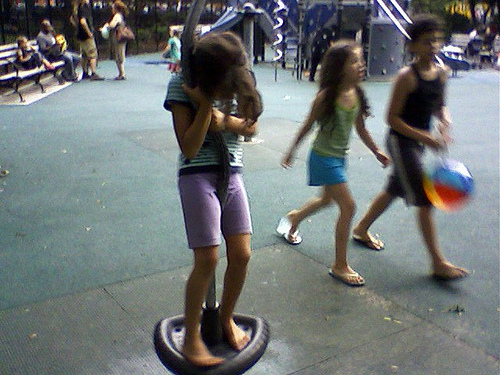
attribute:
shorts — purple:
[181, 165, 253, 242]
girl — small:
[153, 26, 282, 373]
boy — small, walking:
[392, 13, 474, 294]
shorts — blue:
[306, 142, 348, 189]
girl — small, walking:
[295, 30, 368, 265]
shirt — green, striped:
[324, 81, 360, 167]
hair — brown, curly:
[192, 35, 260, 90]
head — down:
[185, 33, 244, 97]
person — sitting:
[15, 32, 42, 70]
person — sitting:
[30, 20, 79, 71]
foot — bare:
[220, 312, 251, 351]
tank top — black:
[403, 58, 451, 143]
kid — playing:
[161, 17, 183, 71]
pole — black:
[169, 11, 228, 330]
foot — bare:
[178, 327, 225, 370]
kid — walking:
[286, 32, 373, 291]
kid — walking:
[385, 13, 465, 287]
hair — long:
[327, 44, 343, 115]